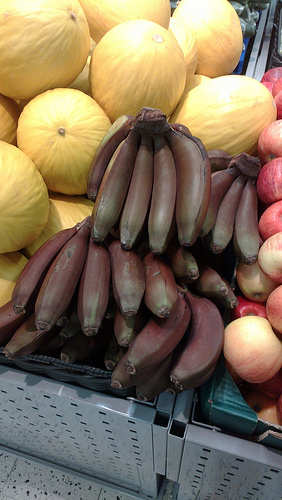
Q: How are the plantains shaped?
A: Like bananas.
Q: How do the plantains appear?
A: Black.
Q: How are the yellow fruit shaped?
A: Oval.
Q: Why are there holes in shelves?
A: Air circulation.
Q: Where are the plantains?
A: Middle.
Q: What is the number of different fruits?
A: Three.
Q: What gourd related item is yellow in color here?
A: Squash.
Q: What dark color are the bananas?
A: Brown.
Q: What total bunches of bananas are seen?
A: Four.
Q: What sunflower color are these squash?
A: Yellow.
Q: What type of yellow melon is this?
A: Squash.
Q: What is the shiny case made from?
A: Metal.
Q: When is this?
A: Daytime.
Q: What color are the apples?
A: Red.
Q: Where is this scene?
A: A farmers market stall.